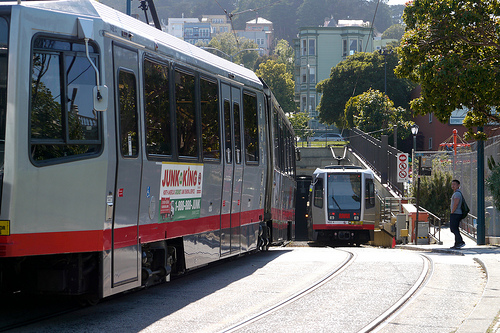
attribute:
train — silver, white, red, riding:
[306, 160, 383, 248]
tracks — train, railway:
[185, 239, 434, 332]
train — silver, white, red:
[2, 0, 305, 325]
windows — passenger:
[135, 52, 177, 159]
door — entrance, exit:
[102, 35, 153, 295]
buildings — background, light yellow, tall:
[296, 20, 380, 143]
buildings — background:
[242, 13, 274, 58]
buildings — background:
[178, 20, 215, 53]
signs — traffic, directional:
[389, 148, 413, 208]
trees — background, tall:
[250, 58, 301, 123]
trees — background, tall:
[202, 28, 257, 70]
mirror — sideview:
[92, 83, 110, 115]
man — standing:
[444, 176, 470, 251]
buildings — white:
[164, 12, 200, 43]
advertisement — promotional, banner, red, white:
[153, 162, 207, 221]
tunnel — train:
[287, 140, 419, 249]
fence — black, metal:
[345, 117, 417, 204]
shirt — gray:
[448, 191, 466, 216]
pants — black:
[448, 211, 470, 246]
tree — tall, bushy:
[314, 38, 419, 144]